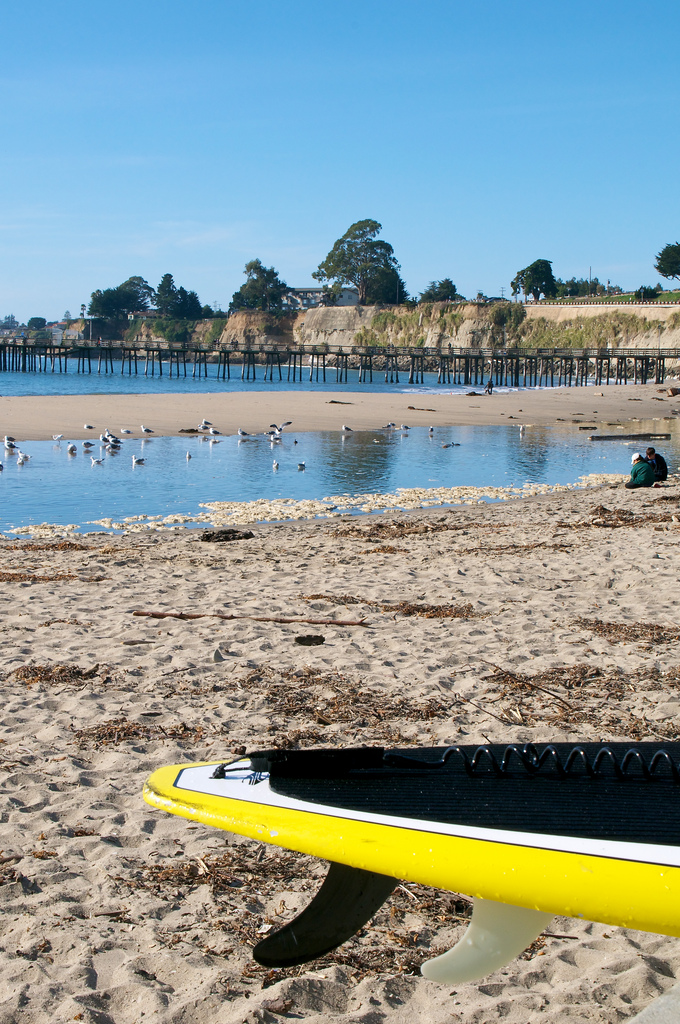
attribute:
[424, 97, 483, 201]
sky — blue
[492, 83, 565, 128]
sky — blue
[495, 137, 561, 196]
sky — blue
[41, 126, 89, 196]
sky — blue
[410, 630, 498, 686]
sand — large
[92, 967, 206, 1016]
sand — large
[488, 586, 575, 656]
sand — large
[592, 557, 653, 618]
sand — large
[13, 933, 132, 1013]
sand — large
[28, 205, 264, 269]
clouds — white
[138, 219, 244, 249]
clouds — white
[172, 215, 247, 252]
clouds — white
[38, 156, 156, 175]
clouds — white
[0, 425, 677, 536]
pond — water